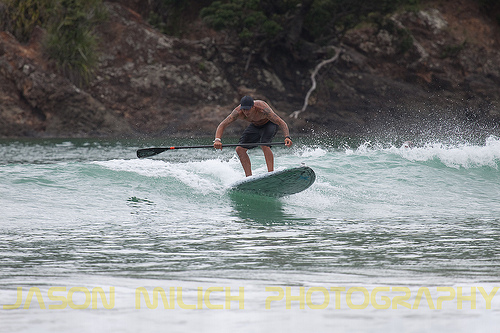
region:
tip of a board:
[304, 169, 313, 173]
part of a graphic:
[246, 275, 308, 316]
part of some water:
[313, 237, 378, 302]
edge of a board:
[233, 155, 289, 187]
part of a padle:
[142, 139, 177, 153]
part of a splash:
[377, 137, 453, 169]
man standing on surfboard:
[198, 84, 321, 212]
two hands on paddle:
[131, 136, 295, 166]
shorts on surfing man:
[227, 114, 288, 158]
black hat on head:
[233, 91, 259, 119]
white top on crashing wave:
[405, 130, 480, 170]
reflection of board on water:
[230, 194, 296, 228]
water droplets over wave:
[400, 108, 466, 143]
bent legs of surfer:
[229, 129, 279, 163]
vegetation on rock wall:
[40, 11, 108, 85]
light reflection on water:
[343, 230, 435, 288]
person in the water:
[206, 91, 336, 187]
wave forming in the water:
[379, 131, 467, 198]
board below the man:
[248, 161, 325, 214]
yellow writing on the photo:
[20, 258, 466, 327]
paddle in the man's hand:
[118, 132, 220, 185]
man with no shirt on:
[207, 79, 292, 154]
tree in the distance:
[258, 1, 357, 51]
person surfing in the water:
[176, 83, 351, 216]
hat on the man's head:
[231, 90, 270, 117]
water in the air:
[411, 102, 466, 136]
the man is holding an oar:
[113, 92, 303, 163]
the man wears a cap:
[233, 87, 257, 115]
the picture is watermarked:
[15, 271, 490, 316]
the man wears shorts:
[232, 116, 288, 155]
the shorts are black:
[239, 111, 284, 153]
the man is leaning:
[192, 79, 302, 175]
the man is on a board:
[205, 82, 318, 219]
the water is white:
[164, 162, 221, 189]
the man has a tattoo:
[264, 102, 279, 124]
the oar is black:
[126, 135, 289, 164]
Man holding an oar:
[126, 126, 307, 154]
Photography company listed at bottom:
[10, 273, 495, 314]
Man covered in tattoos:
[224, 96, 299, 143]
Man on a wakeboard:
[210, 82, 342, 207]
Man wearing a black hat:
[215, 72, 273, 122]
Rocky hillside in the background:
[15, 25, 468, 90]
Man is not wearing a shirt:
[203, 86, 313, 139]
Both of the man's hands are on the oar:
[204, 135, 301, 148]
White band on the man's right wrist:
[200, 132, 233, 155]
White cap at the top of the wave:
[332, 125, 498, 170]